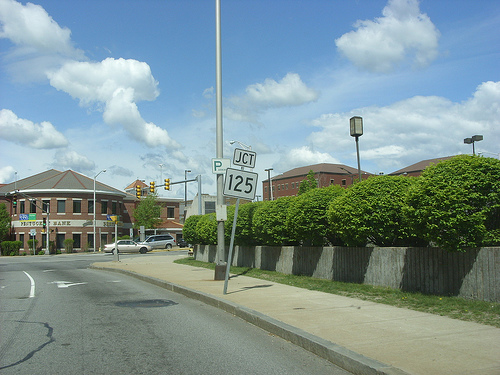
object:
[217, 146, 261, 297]
street sign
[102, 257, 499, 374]
sidewalk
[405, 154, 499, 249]
bush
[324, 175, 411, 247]
bush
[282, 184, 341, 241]
bush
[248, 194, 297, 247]
bush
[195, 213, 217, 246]
bush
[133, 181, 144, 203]
traffic light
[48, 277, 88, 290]
arrow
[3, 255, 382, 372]
street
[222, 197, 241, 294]
pillar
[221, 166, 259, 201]
number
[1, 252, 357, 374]
road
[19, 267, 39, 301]
line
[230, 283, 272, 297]
shadow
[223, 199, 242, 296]
pole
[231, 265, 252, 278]
shadow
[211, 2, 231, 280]
pole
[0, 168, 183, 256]
building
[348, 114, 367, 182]
light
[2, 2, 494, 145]
sky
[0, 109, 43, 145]
clouds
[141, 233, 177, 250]
minivan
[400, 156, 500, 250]
hedges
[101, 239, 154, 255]
sedan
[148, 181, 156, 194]
stoplights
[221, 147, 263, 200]
jct 125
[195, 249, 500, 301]
wall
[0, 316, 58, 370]
crack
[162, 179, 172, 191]
traffic lights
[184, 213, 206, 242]
bushes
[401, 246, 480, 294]
shadows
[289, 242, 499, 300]
fence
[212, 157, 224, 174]
letter p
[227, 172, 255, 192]
125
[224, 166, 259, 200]
sign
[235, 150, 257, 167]
jct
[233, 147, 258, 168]
sign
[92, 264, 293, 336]
curb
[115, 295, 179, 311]
pothole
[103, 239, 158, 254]
cars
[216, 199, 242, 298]
street pole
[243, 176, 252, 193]
numbers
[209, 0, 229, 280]
electric pole